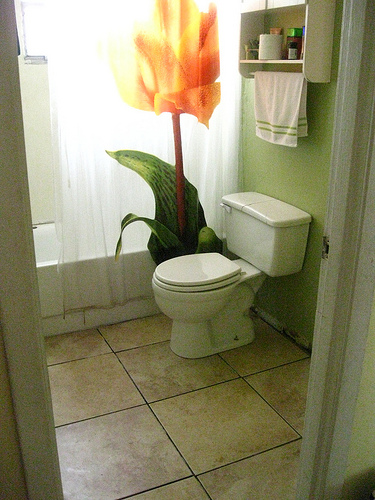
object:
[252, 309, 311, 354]
bottom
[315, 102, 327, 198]
wall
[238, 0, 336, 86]
shelf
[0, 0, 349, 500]
bathroom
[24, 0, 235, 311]
curtain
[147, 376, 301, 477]
tile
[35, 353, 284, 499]
floor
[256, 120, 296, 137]
line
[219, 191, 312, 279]
tank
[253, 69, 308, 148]
towel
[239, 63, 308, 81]
rod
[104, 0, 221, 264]
flower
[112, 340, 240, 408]
tile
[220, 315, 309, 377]
tile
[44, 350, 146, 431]
tile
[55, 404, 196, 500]
tile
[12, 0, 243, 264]
window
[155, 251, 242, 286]
seat cover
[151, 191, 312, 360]
porcelain toilet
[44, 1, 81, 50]
light